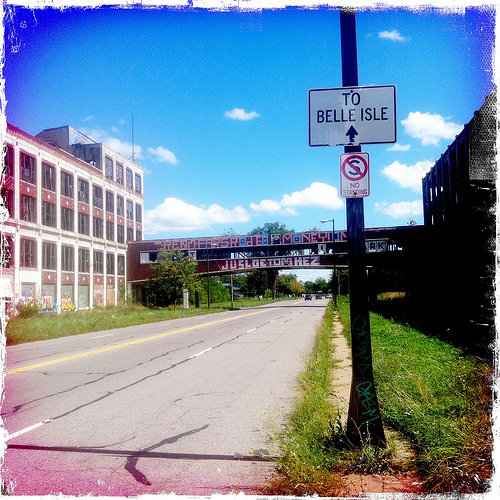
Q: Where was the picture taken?
A: It was taken at the street.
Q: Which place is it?
A: It is a street.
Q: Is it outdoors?
A: Yes, it is outdoors.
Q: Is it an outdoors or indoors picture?
A: It is outdoors.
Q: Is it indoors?
A: No, it is outdoors.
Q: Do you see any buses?
A: No, there are no buses.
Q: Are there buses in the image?
A: No, there are no buses.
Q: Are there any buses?
A: No, there are no buses.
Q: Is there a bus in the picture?
A: No, there are no buses.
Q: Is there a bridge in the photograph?
A: Yes, there is a bridge.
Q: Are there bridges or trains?
A: Yes, there is a bridge.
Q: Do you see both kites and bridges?
A: No, there is a bridge but no kites.